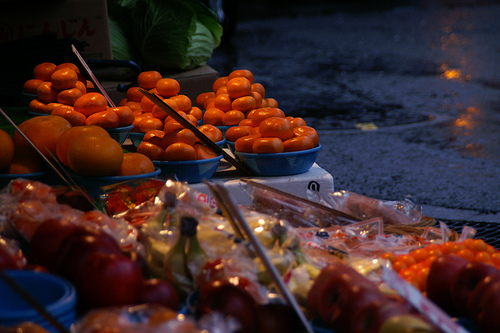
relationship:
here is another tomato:
[257, 116, 297, 141] [252, 137, 284, 154]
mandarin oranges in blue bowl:
[226, 107, 321, 172] [238, 155, 318, 178]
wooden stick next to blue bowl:
[140, 88, 243, 176] [238, 155, 318, 178]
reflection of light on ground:
[337, 3, 498, 190] [419, 1, 499, 171]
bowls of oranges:
[0, 121, 321, 181] [24, 60, 321, 153]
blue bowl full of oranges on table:
[238, 155, 318, 178] [209, 177, 332, 196]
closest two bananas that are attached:
[134, 194, 322, 266] [160, 216, 209, 276]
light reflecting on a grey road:
[419, 1, 499, 171] [337, 3, 498, 190]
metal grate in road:
[354, 122, 382, 134] [337, 3, 498, 190]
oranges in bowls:
[24, 60, 321, 153] [0, 121, 321, 181]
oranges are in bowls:
[24, 60, 321, 153] [0, 121, 321, 181]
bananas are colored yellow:
[145, 192, 216, 277] [134, 194, 322, 266]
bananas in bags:
[145, 192, 216, 277] [134, 194, 322, 266]